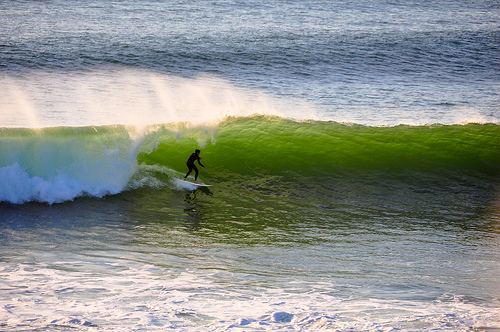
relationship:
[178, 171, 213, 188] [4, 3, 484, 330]
surfboard in water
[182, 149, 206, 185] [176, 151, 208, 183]
man wearing wetsuit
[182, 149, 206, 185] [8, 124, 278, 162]
man riding a wave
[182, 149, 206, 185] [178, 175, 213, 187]
man on a surfboard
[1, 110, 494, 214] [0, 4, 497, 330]
wave in ocean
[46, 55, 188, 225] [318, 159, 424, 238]
wave in ocean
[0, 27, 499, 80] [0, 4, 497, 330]
wave in ocean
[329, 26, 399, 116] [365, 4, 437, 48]
wave in ocean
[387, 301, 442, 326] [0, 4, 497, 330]
wave in ocean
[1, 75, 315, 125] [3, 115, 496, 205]
white spray from crashing waves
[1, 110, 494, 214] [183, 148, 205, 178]
wave headed for surfer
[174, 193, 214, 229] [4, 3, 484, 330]
reflection on water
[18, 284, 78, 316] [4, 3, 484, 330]
ripples in water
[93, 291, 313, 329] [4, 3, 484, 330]
ripples in water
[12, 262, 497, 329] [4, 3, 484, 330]
ripples in water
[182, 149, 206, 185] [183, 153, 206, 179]
man wearing wet suit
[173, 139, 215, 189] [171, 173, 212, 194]
man on surfboard